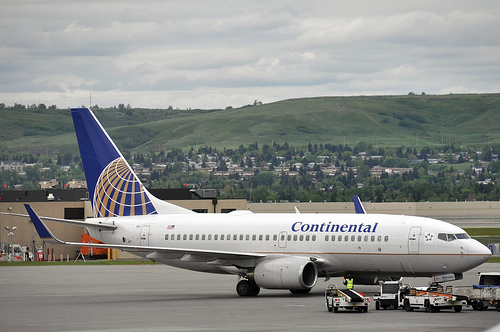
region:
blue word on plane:
[289, 212, 381, 236]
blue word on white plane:
[291, 214, 380, 238]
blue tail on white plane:
[65, 99, 157, 219]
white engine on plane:
[256, 256, 322, 292]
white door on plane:
[406, 222, 423, 256]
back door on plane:
[132, 223, 154, 246]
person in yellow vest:
[339, 273, 359, 298]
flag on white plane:
[164, 217, 177, 232]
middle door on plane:
[277, 227, 291, 249]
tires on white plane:
[235, 277, 262, 297]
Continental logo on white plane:
[289, 220, 379, 234]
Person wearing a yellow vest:
[341, 271, 355, 289]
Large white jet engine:
[251, 256, 316, 289]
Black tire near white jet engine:
[235, 278, 253, 297]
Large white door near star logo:
[407, 221, 422, 252]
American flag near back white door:
[166, 221, 176, 228]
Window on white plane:
[162, 233, 169, 241]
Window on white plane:
[383, 233, 388, 242]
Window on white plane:
[324, 230, 331, 242]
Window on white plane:
[265, 232, 270, 243]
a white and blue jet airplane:
[22, 105, 493, 297]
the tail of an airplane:
[69, 107, 171, 222]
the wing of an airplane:
[22, 202, 324, 273]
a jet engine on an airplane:
[250, 254, 319, 295]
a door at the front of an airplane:
[404, 222, 421, 261]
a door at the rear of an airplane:
[137, 220, 152, 249]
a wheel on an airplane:
[231, 274, 263, 300]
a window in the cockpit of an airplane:
[453, 230, 469, 240]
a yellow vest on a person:
[345, 275, 354, 290]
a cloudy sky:
[1, 2, 499, 107]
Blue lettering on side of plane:
[287, 218, 384, 235]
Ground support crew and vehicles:
[320, 268, 498, 321]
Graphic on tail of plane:
[78, 140, 163, 223]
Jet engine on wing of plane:
[241, 248, 327, 294]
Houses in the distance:
[1, 136, 496, 201]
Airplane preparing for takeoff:
[17, 115, 497, 294]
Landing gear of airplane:
[221, 272, 318, 304]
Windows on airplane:
[159, 228, 480, 245]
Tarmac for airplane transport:
[3, 258, 497, 329]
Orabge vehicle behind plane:
[64, 217, 128, 267]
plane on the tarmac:
[13, 108, 496, 304]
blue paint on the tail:
[69, 110, 176, 217]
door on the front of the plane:
[403, 225, 423, 262]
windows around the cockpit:
[431, 226, 481, 245]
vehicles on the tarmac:
[315, 269, 499, 313]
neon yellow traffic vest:
[343, 275, 356, 288]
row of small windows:
[161, 231, 396, 245]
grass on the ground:
[3, 95, 499, 212]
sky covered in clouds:
[0, 1, 499, 118]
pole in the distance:
[86, 88, 94, 109]